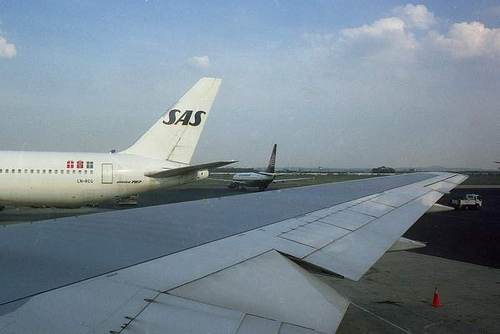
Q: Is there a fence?
A: No, there are no fences.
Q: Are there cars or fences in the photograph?
A: No, there are no fences or cars.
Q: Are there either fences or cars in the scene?
A: No, there are no fences or cars.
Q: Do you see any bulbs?
A: No, there are no bulbs.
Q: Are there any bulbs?
A: No, there are no bulbs.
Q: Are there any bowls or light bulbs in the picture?
A: No, there are no light bulbs or bowls.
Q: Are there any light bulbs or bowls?
A: No, there are no light bulbs or bowls.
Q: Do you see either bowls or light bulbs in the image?
A: No, there are no light bulbs or bowls.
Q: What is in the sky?
A: The clouds are in the sky.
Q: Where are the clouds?
A: The clouds are in the sky.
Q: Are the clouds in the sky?
A: Yes, the clouds are in the sky.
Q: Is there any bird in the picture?
A: No, there are no birds.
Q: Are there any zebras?
A: No, there are no zebras.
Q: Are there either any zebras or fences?
A: No, there are no zebras or fences.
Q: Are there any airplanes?
A: Yes, there is an airplane.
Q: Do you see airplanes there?
A: Yes, there is an airplane.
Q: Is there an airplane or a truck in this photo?
A: Yes, there is an airplane.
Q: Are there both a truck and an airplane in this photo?
A: Yes, there are both an airplane and a truck.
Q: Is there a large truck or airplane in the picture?
A: Yes, there is a large airplane.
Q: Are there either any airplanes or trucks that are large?
A: Yes, the airplane is large.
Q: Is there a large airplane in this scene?
A: Yes, there is a large airplane.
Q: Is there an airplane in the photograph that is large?
A: Yes, there is an airplane that is large.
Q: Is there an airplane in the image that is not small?
A: Yes, there is a large airplane.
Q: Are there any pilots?
A: No, there are no pilots.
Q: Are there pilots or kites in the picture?
A: No, there are no pilots or kites.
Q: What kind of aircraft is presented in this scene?
A: The aircraft is an airplane.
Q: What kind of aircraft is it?
A: The aircraft is an airplane.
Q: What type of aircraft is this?
A: This is an airplane.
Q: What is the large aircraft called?
A: The aircraft is an airplane.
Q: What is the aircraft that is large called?
A: The aircraft is an airplane.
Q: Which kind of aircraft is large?
A: The aircraft is an airplane.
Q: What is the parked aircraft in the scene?
A: The aircraft is an airplane.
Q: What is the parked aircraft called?
A: The aircraft is an airplane.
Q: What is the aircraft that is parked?
A: The aircraft is an airplane.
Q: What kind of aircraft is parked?
A: The aircraft is an airplane.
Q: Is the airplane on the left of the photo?
A: Yes, the airplane is on the left of the image.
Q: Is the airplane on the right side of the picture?
A: No, the airplane is on the left of the image.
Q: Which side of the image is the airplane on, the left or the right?
A: The airplane is on the left of the image.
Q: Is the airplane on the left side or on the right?
A: The airplane is on the left of the image.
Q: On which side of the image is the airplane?
A: The airplane is on the left of the image.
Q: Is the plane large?
A: Yes, the plane is large.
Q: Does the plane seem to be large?
A: Yes, the plane is large.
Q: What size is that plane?
A: The plane is large.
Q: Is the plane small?
A: No, the plane is large.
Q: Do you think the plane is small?
A: No, the plane is large.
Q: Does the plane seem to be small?
A: No, the plane is large.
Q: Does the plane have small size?
A: No, the plane is large.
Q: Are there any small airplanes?
A: No, there is an airplane but it is large.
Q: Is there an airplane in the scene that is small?
A: No, there is an airplane but it is large.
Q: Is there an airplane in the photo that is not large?
A: No, there is an airplane but it is large.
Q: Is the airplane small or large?
A: The airplane is large.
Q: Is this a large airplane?
A: Yes, this is a large airplane.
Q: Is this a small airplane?
A: No, this is a large airplane.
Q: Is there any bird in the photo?
A: No, there are no birds.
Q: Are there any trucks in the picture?
A: Yes, there is a truck.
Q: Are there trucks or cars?
A: Yes, there is a truck.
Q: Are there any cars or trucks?
A: Yes, there is a truck.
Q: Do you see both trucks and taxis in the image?
A: No, there is a truck but no taxis.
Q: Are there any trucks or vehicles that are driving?
A: Yes, the truck is driving.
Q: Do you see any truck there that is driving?
A: Yes, there is a truck that is driving.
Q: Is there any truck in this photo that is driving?
A: Yes, there is a truck that is driving.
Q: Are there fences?
A: No, there are no fences.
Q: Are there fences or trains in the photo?
A: No, there are no fences or trains.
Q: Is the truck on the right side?
A: Yes, the truck is on the right of the image.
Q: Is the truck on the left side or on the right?
A: The truck is on the right of the image.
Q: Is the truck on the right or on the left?
A: The truck is on the right of the image.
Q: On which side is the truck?
A: The truck is on the right of the image.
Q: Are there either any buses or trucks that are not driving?
A: No, there is a truck but it is driving.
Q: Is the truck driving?
A: Yes, the truck is driving.